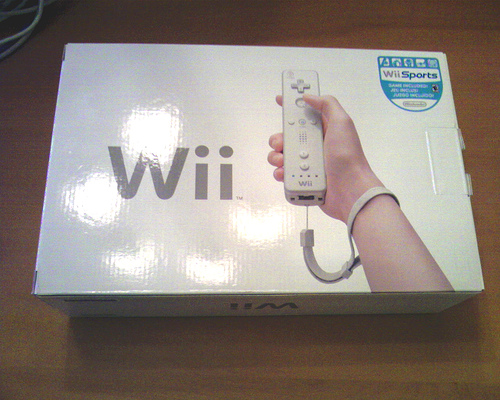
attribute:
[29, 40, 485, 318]
box — white., shiny.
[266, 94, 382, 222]
hand — white.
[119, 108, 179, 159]
glare — light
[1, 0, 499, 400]
table. — tan., wood.